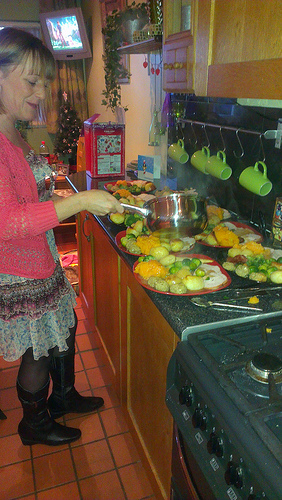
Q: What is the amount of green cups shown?
A: 4.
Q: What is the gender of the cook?
A: The woman.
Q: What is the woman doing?
A: Preparing plates of food.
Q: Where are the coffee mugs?
A: Hanging from a rack over the counter.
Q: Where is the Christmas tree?
A: In the back corner.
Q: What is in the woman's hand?
A: A pot.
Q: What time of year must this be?
A: Christmas.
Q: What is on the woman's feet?
A: Black boots.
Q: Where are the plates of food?
A: On the counter.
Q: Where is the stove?
A: To the right of the counter.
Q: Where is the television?
A: On the wall above the tree.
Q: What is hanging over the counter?
A: Green mugs.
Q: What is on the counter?
A: Plates of food.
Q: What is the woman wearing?
A: A pink sweater.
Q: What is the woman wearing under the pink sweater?
A: A dress.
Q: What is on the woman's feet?
A: Black boots.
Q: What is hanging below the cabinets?
A: A cup rack with mugs.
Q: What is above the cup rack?
A: Cabinets.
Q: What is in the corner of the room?
A: Tv.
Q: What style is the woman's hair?
A: Medium length with bangs.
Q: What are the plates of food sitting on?
A: A counter.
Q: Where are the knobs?
A: On stove.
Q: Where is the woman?
A: In the kitchen.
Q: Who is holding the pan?
A: A woman.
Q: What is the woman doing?
A: Pouring from a pan.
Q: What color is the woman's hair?
A: Blonde.